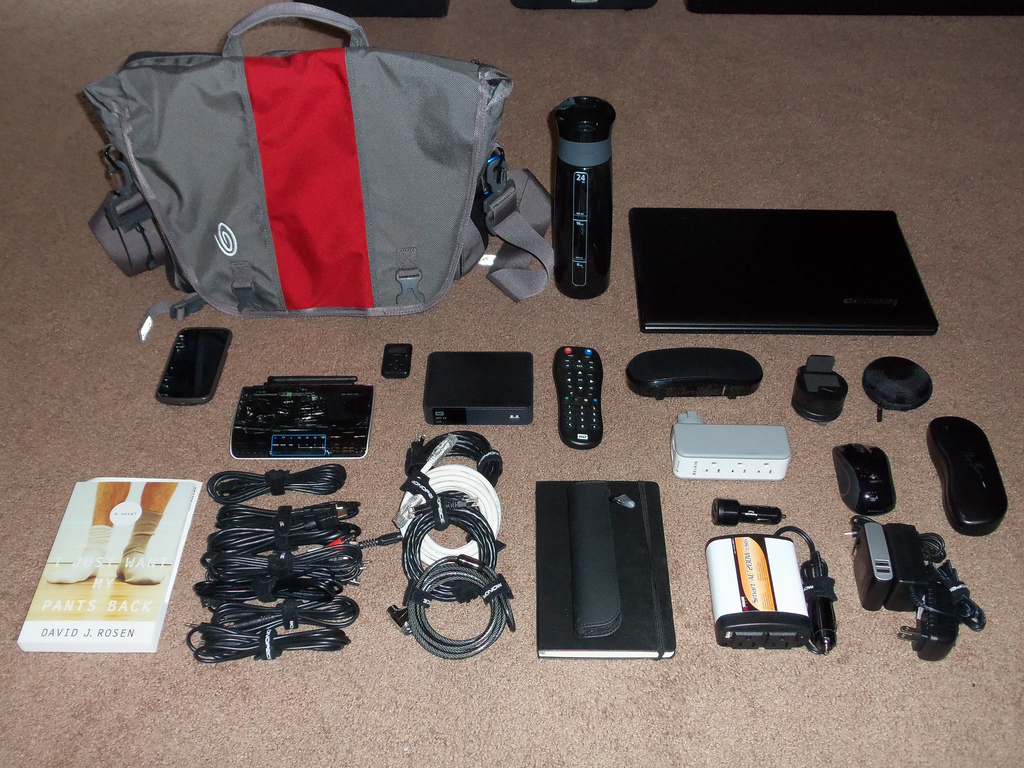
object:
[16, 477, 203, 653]
book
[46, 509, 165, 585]
socks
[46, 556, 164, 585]
feet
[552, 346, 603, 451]
remote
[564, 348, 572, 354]
button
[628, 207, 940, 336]
laptop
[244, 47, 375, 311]
stripe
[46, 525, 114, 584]
sock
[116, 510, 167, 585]
sock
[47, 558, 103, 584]
foot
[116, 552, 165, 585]
foot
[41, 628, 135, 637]
name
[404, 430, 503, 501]
cord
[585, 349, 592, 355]
button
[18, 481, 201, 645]
top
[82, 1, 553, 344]
bag